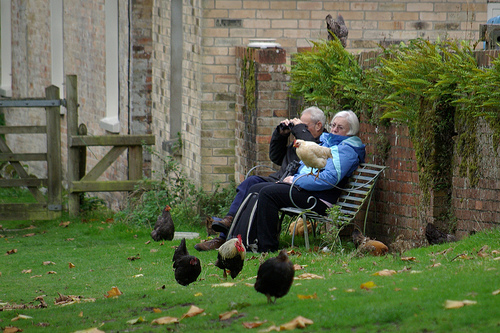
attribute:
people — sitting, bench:
[223, 87, 390, 256]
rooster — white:
[292, 135, 340, 180]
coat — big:
[295, 133, 364, 201]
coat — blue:
[295, 139, 369, 199]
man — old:
[208, 108, 322, 234]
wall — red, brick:
[290, 51, 480, 247]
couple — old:
[205, 110, 360, 259]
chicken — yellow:
[294, 139, 337, 180]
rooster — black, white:
[213, 231, 250, 283]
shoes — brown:
[195, 211, 230, 251]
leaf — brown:
[441, 300, 474, 308]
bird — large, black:
[172, 238, 205, 294]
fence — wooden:
[4, 76, 152, 214]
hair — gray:
[335, 110, 360, 137]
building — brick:
[150, 5, 477, 212]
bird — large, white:
[287, 135, 333, 171]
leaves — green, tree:
[383, 58, 440, 93]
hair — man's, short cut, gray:
[302, 106, 326, 127]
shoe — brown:
[193, 234, 223, 250]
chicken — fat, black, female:
[250, 247, 296, 304]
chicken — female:
[215, 233, 250, 281]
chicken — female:
[169, 236, 203, 291]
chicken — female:
[147, 201, 178, 247]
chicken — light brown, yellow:
[288, 137, 333, 175]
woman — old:
[253, 108, 365, 254]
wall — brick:
[208, 2, 443, 71]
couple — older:
[193, 105, 365, 252]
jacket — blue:
[293, 131, 367, 193]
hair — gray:
[327, 110, 359, 142]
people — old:
[196, 104, 370, 258]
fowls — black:
[140, 204, 205, 294]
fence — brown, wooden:
[0, 72, 157, 226]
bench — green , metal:
[242, 153, 384, 257]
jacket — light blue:
[285, 132, 365, 195]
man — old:
[200, 106, 329, 251]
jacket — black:
[267, 116, 327, 175]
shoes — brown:
[195, 231, 232, 255]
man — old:
[264, 104, 328, 174]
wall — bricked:
[234, 35, 443, 249]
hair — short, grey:
[324, 107, 361, 144]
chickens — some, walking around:
[148, 200, 305, 301]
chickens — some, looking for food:
[142, 200, 295, 303]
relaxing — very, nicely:
[194, 100, 385, 249]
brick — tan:
[364, 11, 394, 21]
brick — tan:
[338, 10, 367, 20]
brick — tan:
[282, 10, 311, 21]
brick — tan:
[270, 17, 298, 34]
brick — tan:
[238, 18, 270, 31]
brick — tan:
[198, 28, 230, 39]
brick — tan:
[203, 63, 231, 78]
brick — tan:
[200, 155, 230, 167]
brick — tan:
[405, 3, 434, 13]